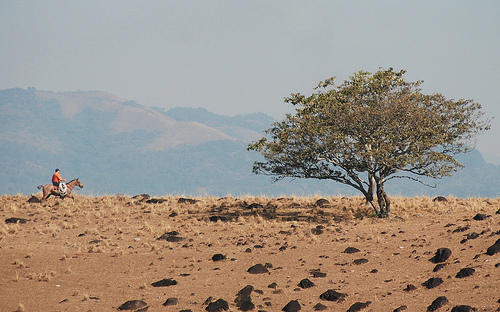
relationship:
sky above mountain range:
[1, 0, 500, 166] [0, 87, 499, 199]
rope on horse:
[59, 182, 68, 195] [37, 178, 84, 201]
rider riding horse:
[51, 169, 66, 192] [37, 178, 84, 201]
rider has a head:
[51, 169, 66, 192] [55, 169, 60, 174]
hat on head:
[56, 168, 61, 171] [55, 169, 60, 174]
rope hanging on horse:
[59, 182, 68, 195] [37, 178, 84, 201]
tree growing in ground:
[246, 67, 495, 219] [0, 196, 499, 312]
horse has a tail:
[37, 178, 84, 201] [37, 184, 44, 190]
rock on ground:
[281, 301, 301, 312] [0, 196, 499, 312]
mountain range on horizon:
[0, 87, 499, 199] [0, 87, 500, 168]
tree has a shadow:
[246, 67, 495, 219] [188, 203, 378, 225]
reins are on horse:
[64, 181, 82, 190] [37, 178, 84, 201]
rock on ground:
[297, 278, 316, 289] [0, 196, 499, 312]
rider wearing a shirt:
[51, 169, 66, 192] [52, 172, 61, 182]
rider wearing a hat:
[51, 169, 66, 192] [56, 168, 61, 171]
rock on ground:
[313, 303, 328, 312] [0, 196, 499, 312]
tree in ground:
[246, 67, 495, 219] [0, 196, 499, 312]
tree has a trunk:
[246, 67, 495, 219] [360, 187, 380, 215]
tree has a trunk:
[246, 67, 495, 219] [376, 185, 387, 214]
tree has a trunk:
[246, 67, 495, 219] [381, 187, 390, 212]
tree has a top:
[246, 67, 495, 219] [246, 67, 495, 189]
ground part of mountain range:
[0, 196, 499, 312] [0, 87, 499, 199]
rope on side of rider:
[59, 182, 68, 195] [51, 169, 66, 192]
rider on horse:
[51, 169, 66, 192] [37, 178, 84, 201]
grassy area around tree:
[0, 192, 500, 227] [246, 67, 495, 219]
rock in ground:
[281, 301, 301, 312] [0, 196, 499, 312]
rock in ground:
[297, 278, 316, 289] [0, 196, 499, 312]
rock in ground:
[313, 303, 328, 312] [0, 196, 499, 312]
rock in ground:
[319, 289, 345, 301] [0, 196, 499, 312]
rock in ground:
[347, 301, 372, 312] [0, 196, 499, 312]